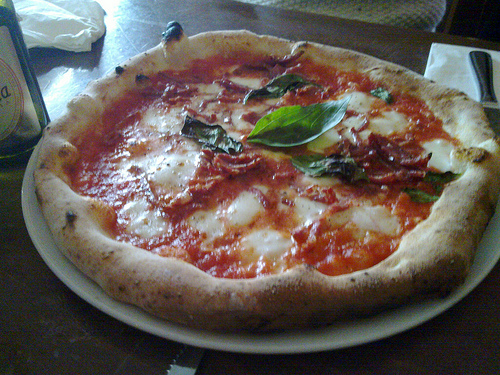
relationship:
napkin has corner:
[420, 41, 500, 104] [422, 31, 452, 57]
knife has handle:
[468, 49, 500, 140] [466, 49, 497, 103]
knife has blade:
[164, 345, 206, 373] [163, 344, 184, 374]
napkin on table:
[11, 2, 106, 52] [0, 0, 500, 373]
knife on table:
[469, 48, 499, 137] [0, 0, 500, 373]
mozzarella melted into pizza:
[114, 62, 419, 262] [34, 12, 499, 301]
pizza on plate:
[31, 23, 498, 332] [23, 53, 498, 352]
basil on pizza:
[176, 68, 369, 180] [29, 18, 499, 335]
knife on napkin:
[468, 49, 500, 140] [424, 47, 497, 97]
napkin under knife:
[420, 46, 499, 85] [468, 49, 500, 140]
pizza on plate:
[29, 18, 499, 335] [20, 136, 498, 354]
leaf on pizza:
[247, 99, 354, 153] [29, 18, 499, 335]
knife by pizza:
[468, 49, 500, 140] [29, 18, 499, 335]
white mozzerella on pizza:
[132, 136, 199, 191] [58, 37, 455, 298]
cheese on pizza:
[104, 65, 462, 276] [29, 18, 499, 335]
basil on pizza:
[291, 152, 372, 186] [29, 18, 499, 335]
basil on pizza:
[177, 113, 243, 156] [29, 18, 499, 335]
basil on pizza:
[243, 71, 315, 106] [29, 18, 499, 335]